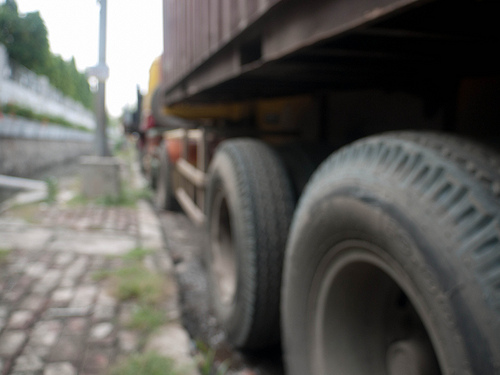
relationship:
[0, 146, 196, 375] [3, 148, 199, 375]
grass inside walkway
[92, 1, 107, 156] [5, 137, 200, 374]
light pole on walkway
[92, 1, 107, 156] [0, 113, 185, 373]
light pole on sidewalk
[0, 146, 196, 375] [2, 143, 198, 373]
grass on pavement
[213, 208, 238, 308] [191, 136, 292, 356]
hub on truck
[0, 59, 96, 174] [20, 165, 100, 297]
stone wall left of sidewalk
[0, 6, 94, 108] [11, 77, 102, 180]
trees left of wall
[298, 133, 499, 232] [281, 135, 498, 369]
tread on tire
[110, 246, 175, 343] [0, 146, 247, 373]
grass in pavement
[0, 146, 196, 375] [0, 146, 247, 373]
grass in pavement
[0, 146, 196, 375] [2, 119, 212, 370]
grass in pavement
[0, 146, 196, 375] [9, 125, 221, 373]
grass in pavement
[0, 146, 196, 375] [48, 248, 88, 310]
grass growing on cracks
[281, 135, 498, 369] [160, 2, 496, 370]
tire on truck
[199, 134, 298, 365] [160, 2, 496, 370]
tire on truck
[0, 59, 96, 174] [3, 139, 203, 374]
stone wall along sidewalk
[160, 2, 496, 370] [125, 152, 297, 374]
truck parked on side of road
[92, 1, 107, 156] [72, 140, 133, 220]
light pole has base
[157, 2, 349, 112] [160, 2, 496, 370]
metal top on truck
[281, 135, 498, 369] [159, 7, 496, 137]
tire on front of truck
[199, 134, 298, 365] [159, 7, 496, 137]
tire on front of truck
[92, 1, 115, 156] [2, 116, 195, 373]
light pole in cement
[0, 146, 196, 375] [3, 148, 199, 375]
grass growing through walkway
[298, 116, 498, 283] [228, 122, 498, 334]
tread on tire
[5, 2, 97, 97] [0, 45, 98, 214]
trees behind wall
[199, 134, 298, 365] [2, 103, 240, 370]
tire on ground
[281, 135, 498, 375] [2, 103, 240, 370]
tire on ground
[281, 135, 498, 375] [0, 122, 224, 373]
tire on ground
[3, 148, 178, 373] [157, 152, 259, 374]
walkway on side of road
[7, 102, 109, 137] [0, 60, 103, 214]
greenery growing through wall